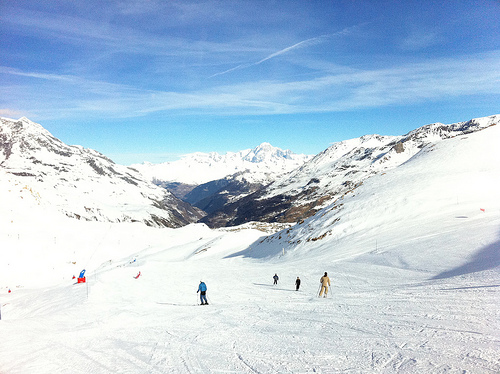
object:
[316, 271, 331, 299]
person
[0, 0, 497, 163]
sky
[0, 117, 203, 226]
hill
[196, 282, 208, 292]
jacket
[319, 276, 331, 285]
jacket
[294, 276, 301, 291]
person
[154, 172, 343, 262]
shade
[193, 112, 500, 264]
mountain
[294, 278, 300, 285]
clothes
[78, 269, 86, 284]
marker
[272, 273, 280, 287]
person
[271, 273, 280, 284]
man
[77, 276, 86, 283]
bench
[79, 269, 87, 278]
flag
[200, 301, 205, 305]
shoe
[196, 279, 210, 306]
skier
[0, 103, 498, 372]
snow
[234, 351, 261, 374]
track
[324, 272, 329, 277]
mask